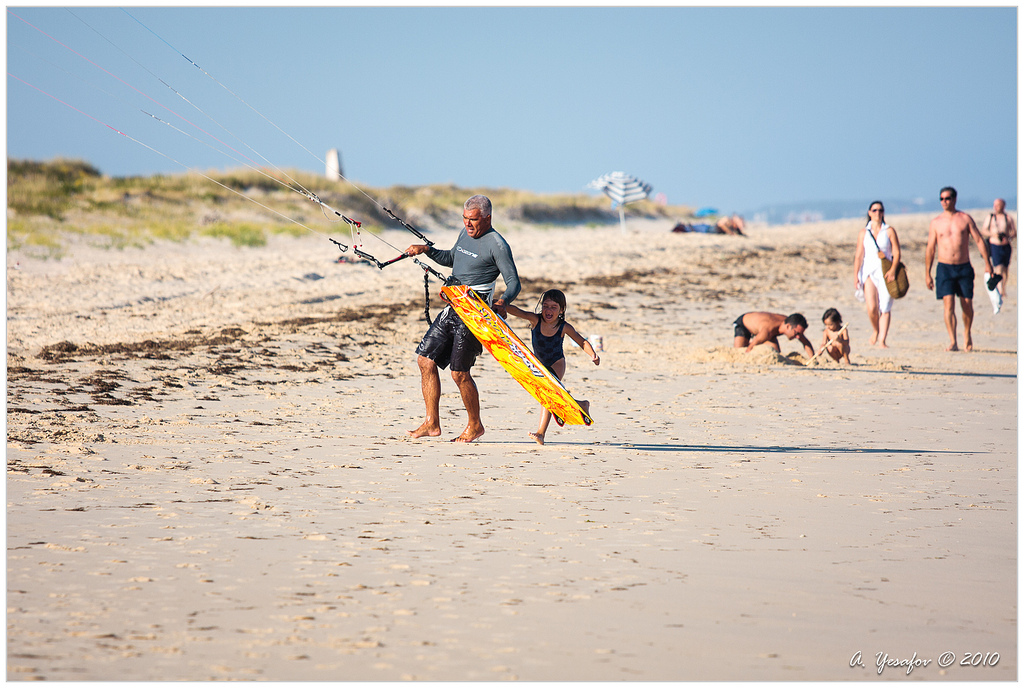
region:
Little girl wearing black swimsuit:
[492, 284, 604, 446]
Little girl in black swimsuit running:
[494, 286, 609, 448]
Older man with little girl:
[403, 191, 609, 452]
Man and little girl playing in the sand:
[715, 303, 856, 371]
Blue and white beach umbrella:
[586, 165, 657, 230]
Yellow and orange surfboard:
[433, 280, 598, 433]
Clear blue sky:
[11, 9, 1015, 219]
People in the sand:
[10, 156, 1020, 679]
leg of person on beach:
[446, 368, 489, 445]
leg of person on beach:
[405, 350, 438, 439]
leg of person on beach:
[532, 403, 552, 448]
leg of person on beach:
[879, 301, 893, 352]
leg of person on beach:
[861, 279, 880, 346]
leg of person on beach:
[943, 295, 963, 357]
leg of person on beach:
[958, 290, 979, 349]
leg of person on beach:
[990, 264, 1011, 296]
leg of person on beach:
[728, 330, 749, 344]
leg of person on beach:
[763, 336, 780, 359]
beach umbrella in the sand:
[587, 161, 656, 232]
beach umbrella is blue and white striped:
[588, 163, 651, 206]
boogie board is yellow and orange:
[437, 282, 596, 439]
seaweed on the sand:
[13, 346, 269, 416]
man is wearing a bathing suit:
[412, 300, 486, 372]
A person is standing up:
[512, 261, 589, 427]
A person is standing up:
[369, 166, 532, 449]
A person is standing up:
[865, 198, 923, 369]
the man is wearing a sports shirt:
[424, 225, 522, 312]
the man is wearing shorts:
[413, 291, 483, 362]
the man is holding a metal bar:
[367, 196, 510, 438]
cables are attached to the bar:
[40, 19, 437, 272]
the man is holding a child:
[493, 293, 599, 440]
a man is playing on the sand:
[723, 303, 815, 373]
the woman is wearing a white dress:
[853, 218, 902, 313]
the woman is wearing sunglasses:
[869, 206, 882, 211]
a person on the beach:
[391, 180, 519, 456]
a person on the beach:
[720, 291, 813, 378]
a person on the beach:
[817, 286, 868, 376]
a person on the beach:
[831, 177, 911, 354]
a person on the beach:
[969, 190, 1008, 305]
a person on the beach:
[428, 174, 518, 425]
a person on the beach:
[714, 209, 754, 241]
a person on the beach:
[723, 282, 816, 365]